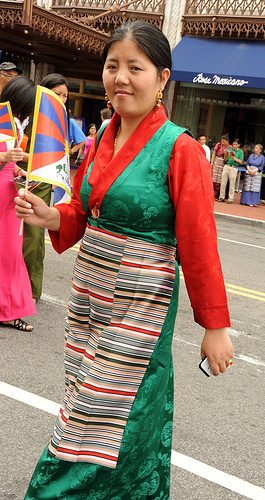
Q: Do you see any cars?
A: No, there are no cars.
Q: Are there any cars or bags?
A: No, there are no cars or bags.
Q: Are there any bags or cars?
A: No, there are no cars or bags.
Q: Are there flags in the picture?
A: Yes, there is a flag.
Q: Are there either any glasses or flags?
A: Yes, there is a flag.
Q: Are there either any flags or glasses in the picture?
A: Yes, there is a flag.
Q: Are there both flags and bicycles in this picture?
A: No, there is a flag but no bicycles.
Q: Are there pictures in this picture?
A: No, there are no pictures.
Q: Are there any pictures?
A: No, there are no pictures.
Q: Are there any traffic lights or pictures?
A: No, there are no pictures or traffic lights.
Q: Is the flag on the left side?
A: Yes, the flag is on the left of the image.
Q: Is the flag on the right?
A: No, the flag is on the left of the image.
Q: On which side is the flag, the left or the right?
A: The flag is on the left of the image.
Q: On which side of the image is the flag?
A: The flag is on the left of the image.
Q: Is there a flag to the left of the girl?
A: Yes, there is a flag to the left of the girl.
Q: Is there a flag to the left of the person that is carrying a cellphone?
A: Yes, there is a flag to the left of the girl.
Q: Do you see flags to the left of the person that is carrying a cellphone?
A: Yes, there is a flag to the left of the girl.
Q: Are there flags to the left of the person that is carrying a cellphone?
A: Yes, there is a flag to the left of the girl.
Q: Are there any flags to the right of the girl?
A: No, the flag is to the left of the girl.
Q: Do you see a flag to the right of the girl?
A: No, the flag is to the left of the girl.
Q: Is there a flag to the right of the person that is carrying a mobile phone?
A: No, the flag is to the left of the girl.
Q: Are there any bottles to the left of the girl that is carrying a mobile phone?
A: No, there is a flag to the left of the girl.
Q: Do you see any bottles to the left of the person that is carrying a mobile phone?
A: No, there is a flag to the left of the girl.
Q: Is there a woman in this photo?
A: Yes, there is a woman.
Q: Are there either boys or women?
A: Yes, there is a woman.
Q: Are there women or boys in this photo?
A: Yes, there is a woman.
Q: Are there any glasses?
A: No, there are no glasses.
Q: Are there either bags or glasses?
A: No, there are no glasses or bags.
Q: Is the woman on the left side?
A: Yes, the woman is on the left of the image.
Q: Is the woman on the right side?
A: No, the woman is on the left of the image.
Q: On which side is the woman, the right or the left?
A: The woman is on the left of the image.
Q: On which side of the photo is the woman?
A: The woman is on the left of the image.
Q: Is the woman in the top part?
A: Yes, the woman is in the top of the image.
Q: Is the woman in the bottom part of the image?
A: No, the woman is in the top of the image.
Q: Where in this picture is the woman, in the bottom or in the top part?
A: The woman is in the top of the image.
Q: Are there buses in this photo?
A: No, there are no buses.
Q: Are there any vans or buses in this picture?
A: No, there are no buses or vans.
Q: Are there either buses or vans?
A: No, there are no buses or vans.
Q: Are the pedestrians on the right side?
A: Yes, the pedestrians are on the right of the image.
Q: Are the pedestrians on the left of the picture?
A: No, the pedestrians are on the right of the image.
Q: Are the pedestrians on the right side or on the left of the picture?
A: The pedestrians are on the right of the image.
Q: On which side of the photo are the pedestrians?
A: The pedestrians are on the right of the image.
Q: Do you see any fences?
A: No, there are no fences.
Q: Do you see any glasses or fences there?
A: No, there are no fences or glasses.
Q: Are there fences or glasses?
A: No, there are no fences or glasses.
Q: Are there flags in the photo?
A: Yes, there is a flag.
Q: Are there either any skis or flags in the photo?
A: Yes, there is a flag.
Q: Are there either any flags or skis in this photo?
A: Yes, there is a flag.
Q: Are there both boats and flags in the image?
A: No, there is a flag but no boats.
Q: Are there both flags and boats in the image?
A: No, there is a flag but no boats.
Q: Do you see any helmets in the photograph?
A: No, there are no helmets.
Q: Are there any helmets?
A: No, there are no helmets.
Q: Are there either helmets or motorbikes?
A: No, there are no helmets or motorbikes.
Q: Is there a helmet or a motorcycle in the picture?
A: No, there are no helmets or motorcycles.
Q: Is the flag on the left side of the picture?
A: Yes, the flag is on the left of the image.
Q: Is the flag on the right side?
A: No, the flag is on the left of the image.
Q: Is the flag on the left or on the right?
A: The flag is on the left of the image.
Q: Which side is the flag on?
A: The flag is on the left of the image.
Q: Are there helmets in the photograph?
A: No, there are no helmets.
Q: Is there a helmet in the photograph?
A: No, there are no helmets.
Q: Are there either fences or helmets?
A: No, there are no helmets or fences.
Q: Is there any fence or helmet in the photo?
A: No, there are no helmets or fences.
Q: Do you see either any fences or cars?
A: No, there are no cars or fences.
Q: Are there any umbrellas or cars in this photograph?
A: No, there are no cars or umbrellas.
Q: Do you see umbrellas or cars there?
A: No, there are no cars or umbrellas.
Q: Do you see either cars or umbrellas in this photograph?
A: No, there are no cars or umbrellas.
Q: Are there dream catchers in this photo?
A: No, there are no dream catchers.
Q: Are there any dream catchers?
A: No, there are no dream catchers.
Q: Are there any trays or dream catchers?
A: No, there are no dream catchers or trays.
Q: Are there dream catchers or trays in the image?
A: No, there are no dream catchers or trays.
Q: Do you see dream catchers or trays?
A: No, there are no dream catchers or trays.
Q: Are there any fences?
A: No, there are no fences.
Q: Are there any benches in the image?
A: No, there are no benches.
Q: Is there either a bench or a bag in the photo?
A: No, there are no benches or bags.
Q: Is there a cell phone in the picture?
A: Yes, there is a cell phone.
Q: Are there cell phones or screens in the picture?
A: Yes, there is a cell phone.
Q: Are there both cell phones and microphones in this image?
A: No, there is a cell phone but no microphones.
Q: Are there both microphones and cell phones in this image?
A: No, there is a cell phone but no microphones.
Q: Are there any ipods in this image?
A: No, there are no ipods.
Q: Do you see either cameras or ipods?
A: No, there are no ipods or cameras.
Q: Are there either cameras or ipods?
A: No, there are no ipods or cameras.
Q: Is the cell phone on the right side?
A: Yes, the cell phone is on the right of the image.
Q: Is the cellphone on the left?
A: No, the cellphone is on the right of the image.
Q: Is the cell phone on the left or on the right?
A: The cell phone is on the right of the image.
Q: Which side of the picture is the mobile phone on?
A: The mobile phone is on the right of the image.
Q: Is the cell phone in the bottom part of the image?
A: Yes, the cell phone is in the bottom of the image.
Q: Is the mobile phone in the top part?
A: No, the mobile phone is in the bottom of the image.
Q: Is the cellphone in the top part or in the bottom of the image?
A: The cellphone is in the bottom of the image.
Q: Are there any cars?
A: No, there are no cars.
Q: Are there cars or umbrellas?
A: No, there are no cars or umbrellas.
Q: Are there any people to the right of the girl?
A: Yes, there are people to the right of the girl.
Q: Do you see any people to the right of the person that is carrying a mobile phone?
A: Yes, there are people to the right of the girl.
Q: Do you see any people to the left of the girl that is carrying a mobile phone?
A: No, the people are to the right of the girl.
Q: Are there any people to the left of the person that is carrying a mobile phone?
A: No, the people are to the right of the girl.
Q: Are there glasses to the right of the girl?
A: No, there are people to the right of the girl.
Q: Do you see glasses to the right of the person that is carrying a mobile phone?
A: No, there are people to the right of the girl.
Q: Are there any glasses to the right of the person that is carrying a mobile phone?
A: No, there are people to the right of the girl.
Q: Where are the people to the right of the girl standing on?
A: The people are standing on the sidewalk.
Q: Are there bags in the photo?
A: No, there are no bags.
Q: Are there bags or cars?
A: No, there are no bags or cars.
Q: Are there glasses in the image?
A: No, there are no glasses.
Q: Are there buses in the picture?
A: No, there are no buses.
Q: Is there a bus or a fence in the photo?
A: No, there are no buses or fences.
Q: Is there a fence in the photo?
A: No, there are no fences.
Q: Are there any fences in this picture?
A: No, there are no fences.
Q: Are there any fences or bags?
A: No, there are no fences or bags.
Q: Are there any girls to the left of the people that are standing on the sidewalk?
A: Yes, there is a girl to the left of the people.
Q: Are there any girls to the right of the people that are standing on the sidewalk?
A: No, the girl is to the left of the people.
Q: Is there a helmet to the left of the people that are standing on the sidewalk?
A: No, there is a girl to the left of the people.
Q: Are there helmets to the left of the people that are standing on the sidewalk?
A: No, there is a girl to the left of the people.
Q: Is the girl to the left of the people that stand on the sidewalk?
A: Yes, the girl is to the left of the people.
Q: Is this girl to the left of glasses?
A: No, the girl is to the left of the people.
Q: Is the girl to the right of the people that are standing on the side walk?
A: No, the girl is to the left of the people.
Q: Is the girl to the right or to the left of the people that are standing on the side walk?
A: The girl is to the left of the people.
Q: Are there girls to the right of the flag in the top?
A: Yes, there is a girl to the right of the flag.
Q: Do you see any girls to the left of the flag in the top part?
A: No, the girl is to the right of the flag.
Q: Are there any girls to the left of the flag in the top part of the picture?
A: No, the girl is to the right of the flag.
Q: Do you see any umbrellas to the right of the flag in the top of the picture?
A: No, there is a girl to the right of the flag.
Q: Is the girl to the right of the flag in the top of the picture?
A: Yes, the girl is to the right of the flag.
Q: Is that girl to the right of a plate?
A: No, the girl is to the right of the flag.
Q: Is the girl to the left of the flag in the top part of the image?
A: No, the girl is to the right of the flag.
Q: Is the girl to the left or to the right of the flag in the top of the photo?
A: The girl is to the right of the flag.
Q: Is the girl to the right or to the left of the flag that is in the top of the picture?
A: The girl is to the right of the flag.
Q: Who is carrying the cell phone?
A: The girl is carrying the cell phone.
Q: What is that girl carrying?
A: The girl is carrying a cellphone.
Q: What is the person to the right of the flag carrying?
A: The girl is carrying a cellphone.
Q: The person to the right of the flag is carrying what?
A: The girl is carrying a cellphone.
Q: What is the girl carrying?
A: The girl is carrying a cellphone.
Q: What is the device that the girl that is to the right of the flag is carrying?
A: The device is a cell phone.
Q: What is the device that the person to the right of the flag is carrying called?
A: The device is a cell phone.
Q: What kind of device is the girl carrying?
A: The girl is carrying a cellphone.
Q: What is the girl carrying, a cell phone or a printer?
A: The girl is carrying a cell phone.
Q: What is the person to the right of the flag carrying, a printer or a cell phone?
A: The girl is carrying a cell phone.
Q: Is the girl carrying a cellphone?
A: Yes, the girl is carrying a cellphone.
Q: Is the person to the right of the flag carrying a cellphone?
A: Yes, the girl is carrying a cellphone.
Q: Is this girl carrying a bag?
A: No, the girl is carrying a cellphone.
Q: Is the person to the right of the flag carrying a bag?
A: No, the girl is carrying a cellphone.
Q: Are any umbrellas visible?
A: No, there are no umbrellas.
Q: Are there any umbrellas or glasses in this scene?
A: No, there are no umbrellas or glasses.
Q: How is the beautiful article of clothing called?
A: The clothing item is a dress.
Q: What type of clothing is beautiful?
A: The clothing is a dress.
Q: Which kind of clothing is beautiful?
A: The clothing is a dress.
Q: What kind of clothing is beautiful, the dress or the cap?
A: The dress is beautiful.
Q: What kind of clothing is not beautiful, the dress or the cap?
A: The cap is not beautiful.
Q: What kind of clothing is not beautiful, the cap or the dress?
A: The cap is not beautiful.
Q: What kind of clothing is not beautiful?
A: The clothing is a cap.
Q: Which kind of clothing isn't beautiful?
A: The clothing is a cap.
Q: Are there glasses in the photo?
A: No, there are no glasses.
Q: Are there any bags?
A: No, there are no bags.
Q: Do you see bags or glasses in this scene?
A: No, there are no bags or glasses.